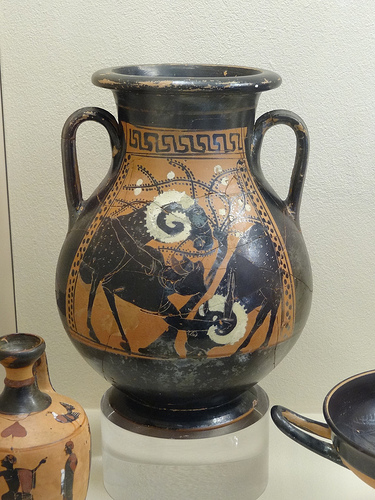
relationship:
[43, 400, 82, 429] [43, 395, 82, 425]
bird of bird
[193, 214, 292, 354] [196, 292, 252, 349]
ram has white horns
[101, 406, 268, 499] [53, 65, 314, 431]
clear stand for vase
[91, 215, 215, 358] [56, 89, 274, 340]
bull on vase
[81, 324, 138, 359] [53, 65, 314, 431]
bull hooves on vase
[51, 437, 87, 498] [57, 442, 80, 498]
drawing of person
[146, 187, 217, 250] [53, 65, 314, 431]
drawing on vase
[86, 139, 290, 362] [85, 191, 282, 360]
picture of rams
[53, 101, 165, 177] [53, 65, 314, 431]
handle of vase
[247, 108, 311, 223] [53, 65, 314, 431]
handle of vase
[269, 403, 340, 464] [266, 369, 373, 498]
handle of vase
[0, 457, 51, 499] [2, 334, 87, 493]
drawing on vase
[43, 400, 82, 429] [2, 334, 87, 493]
bird on vase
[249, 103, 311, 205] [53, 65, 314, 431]
handle on vase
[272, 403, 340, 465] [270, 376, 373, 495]
handle on a vase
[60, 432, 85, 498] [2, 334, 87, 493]
painting on a vase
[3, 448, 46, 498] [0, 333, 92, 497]
painted person on a tan vase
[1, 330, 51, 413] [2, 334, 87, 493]
spout of a vase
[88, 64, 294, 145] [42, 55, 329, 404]
spout of a vase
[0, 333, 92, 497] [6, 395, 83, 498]
tan vase with paintings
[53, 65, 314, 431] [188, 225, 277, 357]
vase with painting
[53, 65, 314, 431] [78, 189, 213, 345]
vase with painting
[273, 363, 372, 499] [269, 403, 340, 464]
vase with handle